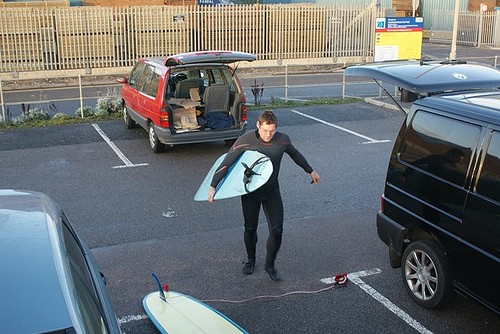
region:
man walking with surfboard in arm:
[192, 108, 322, 285]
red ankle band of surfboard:
[187, 269, 354, 314]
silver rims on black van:
[396, 240, 445, 305]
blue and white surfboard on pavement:
[131, 268, 236, 332]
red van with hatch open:
[111, 42, 257, 147]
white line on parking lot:
[88, 117, 154, 173]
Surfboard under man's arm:
[191, 109, 276, 201]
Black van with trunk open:
[343, 63, 498, 320]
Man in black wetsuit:
[208, 108, 321, 281]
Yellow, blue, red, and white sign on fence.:
[371, 16, 423, 63]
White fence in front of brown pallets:
[0, 4, 419, 66]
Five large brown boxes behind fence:
[0, 5, 325, 67]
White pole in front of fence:
[448, 0, 460, 65]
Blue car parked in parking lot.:
[0, 188, 124, 332]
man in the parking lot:
[188, 86, 320, 277]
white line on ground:
[338, 264, 403, 324]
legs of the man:
[223, 198, 300, 273]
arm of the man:
[281, 123, 333, 193]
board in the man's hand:
[171, 141, 277, 211]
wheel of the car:
[362, 207, 476, 329]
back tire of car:
[126, 115, 172, 175]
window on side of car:
[387, 108, 478, 186]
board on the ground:
[128, 270, 233, 332]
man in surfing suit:
[214, 100, 324, 290]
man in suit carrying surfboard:
[194, 109, 313, 281]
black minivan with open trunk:
[348, 55, 496, 324]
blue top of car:
[2, 185, 123, 330]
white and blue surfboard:
[129, 270, 254, 332]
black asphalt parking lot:
[4, 104, 496, 332]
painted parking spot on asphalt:
[3, 123, 150, 183]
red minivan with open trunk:
[121, 48, 251, 146]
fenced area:
[2, 13, 495, 119]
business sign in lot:
[371, 11, 429, 61]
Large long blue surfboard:
[192, 144, 272, 199]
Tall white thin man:
[206, 109, 317, 284]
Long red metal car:
[121, 49, 247, 156]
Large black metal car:
[341, 56, 498, 310]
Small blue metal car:
[1, 187, 118, 330]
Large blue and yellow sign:
[372, 16, 425, 63]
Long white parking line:
[91, 121, 151, 168]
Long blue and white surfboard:
[141, 272, 256, 332]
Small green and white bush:
[91, 91, 121, 118]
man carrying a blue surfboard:
[191, 108, 323, 281]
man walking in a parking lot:
[205, 107, 321, 282]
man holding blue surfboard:
[192, 105, 321, 286]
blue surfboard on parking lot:
[140, 265, 248, 332]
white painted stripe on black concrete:
[87, 120, 150, 168]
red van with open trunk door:
[115, 47, 257, 153]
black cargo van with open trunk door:
[342, 55, 499, 327]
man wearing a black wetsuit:
[208, 107, 320, 284]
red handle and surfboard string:
[189, 271, 351, 304]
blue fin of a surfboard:
[149, 270, 166, 300]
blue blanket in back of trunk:
[197, 106, 234, 131]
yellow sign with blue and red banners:
[372, 14, 424, 63]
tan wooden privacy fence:
[0, 0, 396, 80]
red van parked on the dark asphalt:
[113, 48, 257, 153]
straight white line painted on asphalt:
[88, 118, 150, 172]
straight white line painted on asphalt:
[287, 103, 390, 144]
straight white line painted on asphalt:
[330, 269, 432, 332]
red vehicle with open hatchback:
[114, 46, 256, 151]